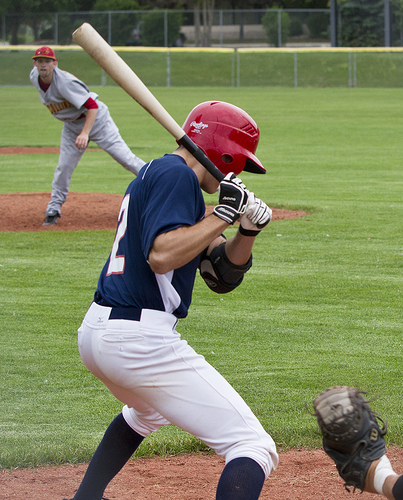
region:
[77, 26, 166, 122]
this is a bat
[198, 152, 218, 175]
the handle is brown in color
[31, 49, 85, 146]
this is a man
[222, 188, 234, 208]
this is a glove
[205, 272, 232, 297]
this is a elbow guard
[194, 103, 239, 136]
this is a helmet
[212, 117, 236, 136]
the helmet is red in color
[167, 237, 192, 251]
the man has a light skin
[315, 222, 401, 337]
this is a grass area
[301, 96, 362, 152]
the grass is green in color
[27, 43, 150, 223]
Baseball player just pitched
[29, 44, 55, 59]
Red hat on baseball pitcher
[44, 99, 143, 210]
Gray pants on baseball pitcher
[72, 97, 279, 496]
Baseball batter looking at pitch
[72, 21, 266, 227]
Brown and black bat held by baseball batter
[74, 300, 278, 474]
White pants on baseball batter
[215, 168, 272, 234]
Black and white batting gloves on baseball player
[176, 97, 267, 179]
Red helmet on baseball batter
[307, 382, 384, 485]
Black mitt of baseball catcher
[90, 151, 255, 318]
Blue jersey with white numeral of baseball batter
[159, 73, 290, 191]
Player is wearing a red helmet.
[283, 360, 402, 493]
The catcher's mitt is showing.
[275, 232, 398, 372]
The grass looks healthy and green.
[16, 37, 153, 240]
The pitcher is getting ready.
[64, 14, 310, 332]
The player is holding a bat.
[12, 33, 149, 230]
The pitcher is wearing a red hat.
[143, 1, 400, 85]
There is a fence in the background.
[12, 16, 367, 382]
This is a baseball game.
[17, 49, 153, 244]
The pitcher is wearing grey.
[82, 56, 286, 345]
The batter is wearing blue.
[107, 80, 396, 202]
The grass is green.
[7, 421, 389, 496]
The ground is brown.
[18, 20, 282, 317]
The people are playing baseball.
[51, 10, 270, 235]
The man is holding a baseball bat in his hands.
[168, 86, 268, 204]
the player has a helmet on.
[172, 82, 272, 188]
the helmet is red.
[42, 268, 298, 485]
the player's pants are white.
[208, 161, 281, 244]
The player is wearing gloves.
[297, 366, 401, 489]
The mitt is black.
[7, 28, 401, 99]
Chain link fence in background.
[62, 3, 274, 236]
wooden baseball bat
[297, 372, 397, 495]
baseball catchers mit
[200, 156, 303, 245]
black and white batting gloves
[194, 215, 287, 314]
black and white elbow brace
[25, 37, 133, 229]
man on pitchers mound pitching ball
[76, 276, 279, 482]
white baseball uniform pants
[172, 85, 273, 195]
hard red batters helmet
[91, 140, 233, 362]
dark blue baseball jersey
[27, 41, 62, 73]
red and yellow baseball cap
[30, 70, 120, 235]
gray baseball uniform with red and yellow detail